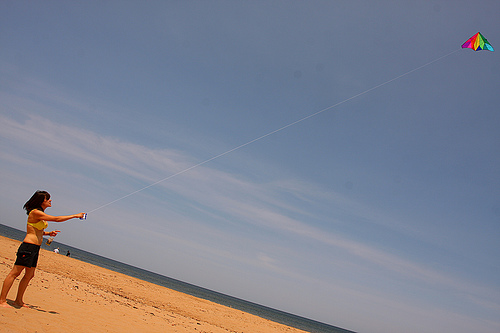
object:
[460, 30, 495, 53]
kite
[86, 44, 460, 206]
string attached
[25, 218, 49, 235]
top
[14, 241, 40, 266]
shorts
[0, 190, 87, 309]
kite flyer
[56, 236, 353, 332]
beach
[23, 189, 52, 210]
hair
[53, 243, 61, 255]
man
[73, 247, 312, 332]
shoreline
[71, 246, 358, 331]
ocean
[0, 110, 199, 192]
clouds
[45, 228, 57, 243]
bottle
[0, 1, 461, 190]
sky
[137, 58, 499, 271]
sky